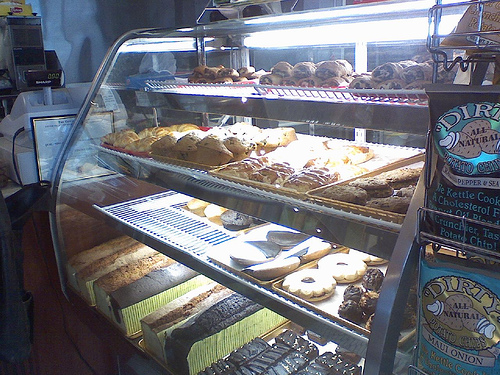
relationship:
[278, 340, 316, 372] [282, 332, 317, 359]
icing on brownies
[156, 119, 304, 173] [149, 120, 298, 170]
tray of muffins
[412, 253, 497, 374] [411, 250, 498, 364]
logo on bag of chips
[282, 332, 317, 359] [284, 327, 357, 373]
brownies topped with nuts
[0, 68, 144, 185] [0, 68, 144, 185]
cash register on cash register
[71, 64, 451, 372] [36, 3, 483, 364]
doughnuts in case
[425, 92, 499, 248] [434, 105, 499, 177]
bag says natural potatos chip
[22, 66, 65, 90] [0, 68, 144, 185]
screen on register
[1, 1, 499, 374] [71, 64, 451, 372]
picture of bakery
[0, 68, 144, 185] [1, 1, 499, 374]
cash register belongs to store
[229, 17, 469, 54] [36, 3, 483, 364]
light inside case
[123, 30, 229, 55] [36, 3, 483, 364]
light on side of case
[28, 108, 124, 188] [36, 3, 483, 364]
sign next to display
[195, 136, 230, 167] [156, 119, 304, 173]
muffin on tray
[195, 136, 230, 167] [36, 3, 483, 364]
muffin inside case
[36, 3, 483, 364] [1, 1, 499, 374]
display in bakery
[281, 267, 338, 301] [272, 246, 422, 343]
cookies on tray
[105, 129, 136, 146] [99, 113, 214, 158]
croissant on tray